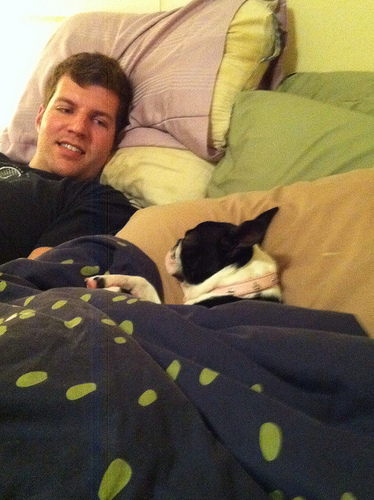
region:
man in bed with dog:
[23, 38, 308, 355]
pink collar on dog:
[183, 282, 282, 304]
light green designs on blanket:
[72, 352, 283, 464]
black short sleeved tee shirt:
[17, 165, 112, 263]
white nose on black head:
[164, 227, 206, 282]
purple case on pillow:
[128, 10, 212, 106]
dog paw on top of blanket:
[79, 267, 158, 305]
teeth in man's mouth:
[51, 136, 85, 157]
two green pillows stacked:
[245, 68, 370, 175]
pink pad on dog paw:
[82, 275, 97, 295]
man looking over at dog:
[22, 47, 303, 293]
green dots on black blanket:
[51, 330, 339, 484]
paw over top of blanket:
[64, 245, 170, 317]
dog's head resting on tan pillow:
[150, 205, 297, 318]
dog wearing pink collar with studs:
[178, 268, 303, 306]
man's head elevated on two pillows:
[14, 35, 149, 208]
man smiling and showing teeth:
[18, 33, 130, 199]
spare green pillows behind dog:
[145, 22, 359, 296]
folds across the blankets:
[43, 304, 282, 444]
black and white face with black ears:
[152, 202, 289, 287]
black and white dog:
[136, 218, 298, 315]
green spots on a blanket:
[10, 355, 104, 489]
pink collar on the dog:
[194, 259, 285, 298]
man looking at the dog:
[15, 57, 153, 190]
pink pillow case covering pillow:
[2, 8, 224, 142]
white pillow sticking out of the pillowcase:
[223, 4, 283, 157]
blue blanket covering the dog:
[3, 232, 373, 484]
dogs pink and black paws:
[71, 269, 130, 297]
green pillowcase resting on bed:
[213, 80, 372, 188]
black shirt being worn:
[2, 134, 137, 293]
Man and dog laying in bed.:
[4, 47, 290, 315]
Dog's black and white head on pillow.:
[152, 196, 311, 325]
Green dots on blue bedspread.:
[11, 352, 103, 411]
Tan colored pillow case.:
[128, 163, 372, 329]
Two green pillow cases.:
[226, 72, 372, 195]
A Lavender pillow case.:
[3, 7, 242, 168]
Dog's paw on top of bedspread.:
[82, 269, 141, 300]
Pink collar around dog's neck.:
[191, 272, 286, 301]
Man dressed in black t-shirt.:
[1, 153, 131, 282]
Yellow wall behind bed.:
[297, 8, 372, 61]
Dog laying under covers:
[154, 217, 266, 362]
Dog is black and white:
[162, 262, 320, 302]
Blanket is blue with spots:
[33, 293, 244, 411]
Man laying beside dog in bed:
[39, 88, 234, 285]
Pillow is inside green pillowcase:
[234, 111, 331, 155]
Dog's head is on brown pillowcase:
[157, 156, 329, 240]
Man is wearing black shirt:
[17, 190, 81, 248]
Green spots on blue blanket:
[45, 317, 286, 492]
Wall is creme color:
[306, 28, 349, 47]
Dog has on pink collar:
[201, 261, 295, 295]